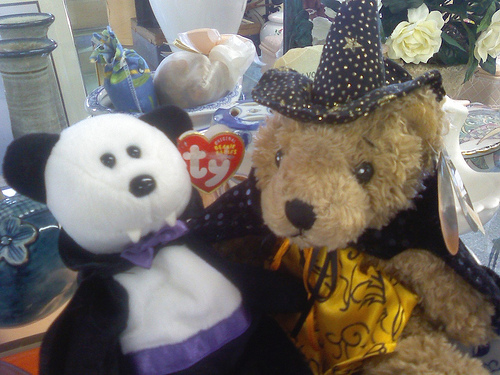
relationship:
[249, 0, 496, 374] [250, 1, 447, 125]
bear wearing hat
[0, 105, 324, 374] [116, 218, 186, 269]
bear wearing tie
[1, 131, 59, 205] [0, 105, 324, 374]
ear of bear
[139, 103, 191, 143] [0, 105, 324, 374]
ear of bear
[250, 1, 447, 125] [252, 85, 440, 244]
hat on head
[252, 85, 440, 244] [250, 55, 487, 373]
head of bear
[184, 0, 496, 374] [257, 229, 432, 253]
bear with cape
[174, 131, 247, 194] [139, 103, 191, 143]
heart hanging from ear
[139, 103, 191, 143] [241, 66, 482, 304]
ear of bear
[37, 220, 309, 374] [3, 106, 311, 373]
black cape around toy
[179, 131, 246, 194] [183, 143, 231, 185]
heart with ty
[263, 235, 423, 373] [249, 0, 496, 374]
material around bear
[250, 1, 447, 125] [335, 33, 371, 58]
hat has stars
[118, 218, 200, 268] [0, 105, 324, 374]
tie on bear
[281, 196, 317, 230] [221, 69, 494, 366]
nose on bear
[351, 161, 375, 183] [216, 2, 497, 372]
eye of bear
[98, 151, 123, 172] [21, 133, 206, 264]
eye of bear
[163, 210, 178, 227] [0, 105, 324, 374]
fang of bear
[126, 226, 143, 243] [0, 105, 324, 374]
fang of bear